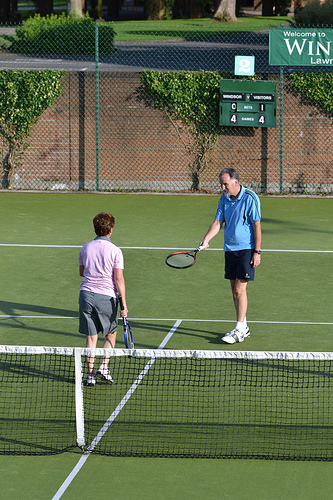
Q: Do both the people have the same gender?
A: No, they are both male and female.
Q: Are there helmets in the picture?
A: No, there are no helmets.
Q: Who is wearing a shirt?
A: The man is wearing a shirt.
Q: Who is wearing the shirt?
A: The man is wearing a shirt.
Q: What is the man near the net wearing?
A: The man is wearing a shirt.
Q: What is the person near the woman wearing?
A: The man is wearing a shirt.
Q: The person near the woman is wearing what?
A: The man is wearing a shirt.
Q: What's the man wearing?
A: The man is wearing a shirt.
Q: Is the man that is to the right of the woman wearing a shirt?
A: Yes, the man is wearing a shirt.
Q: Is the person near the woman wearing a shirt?
A: Yes, the man is wearing a shirt.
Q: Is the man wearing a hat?
A: No, the man is wearing a shirt.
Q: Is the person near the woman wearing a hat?
A: No, the man is wearing a shirt.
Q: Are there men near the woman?
A: Yes, there is a man near the woman.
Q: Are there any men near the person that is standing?
A: Yes, there is a man near the woman.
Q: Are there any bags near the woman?
A: No, there is a man near the woman.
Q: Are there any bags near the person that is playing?
A: No, there is a man near the woman.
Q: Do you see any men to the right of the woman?
A: Yes, there is a man to the right of the woman.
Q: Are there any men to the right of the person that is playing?
A: Yes, there is a man to the right of the woman.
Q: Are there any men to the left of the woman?
A: No, the man is to the right of the woman.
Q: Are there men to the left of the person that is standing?
A: No, the man is to the right of the woman.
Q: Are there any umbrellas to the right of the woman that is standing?
A: No, there is a man to the right of the woman.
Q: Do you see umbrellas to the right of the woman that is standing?
A: No, there is a man to the right of the woman.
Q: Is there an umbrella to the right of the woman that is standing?
A: No, there is a man to the right of the woman.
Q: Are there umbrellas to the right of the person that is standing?
A: No, there is a man to the right of the woman.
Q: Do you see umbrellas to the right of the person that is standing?
A: No, there is a man to the right of the woman.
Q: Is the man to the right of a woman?
A: Yes, the man is to the right of a woman.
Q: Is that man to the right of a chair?
A: No, the man is to the right of a woman.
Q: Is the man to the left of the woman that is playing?
A: No, the man is to the right of the woman.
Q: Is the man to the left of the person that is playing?
A: No, the man is to the right of the woman.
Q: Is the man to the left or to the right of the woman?
A: The man is to the right of the woman.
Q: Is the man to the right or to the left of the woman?
A: The man is to the right of the woman.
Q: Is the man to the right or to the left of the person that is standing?
A: The man is to the right of the woman.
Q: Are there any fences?
A: Yes, there is a fence.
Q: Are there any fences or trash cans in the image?
A: Yes, there is a fence.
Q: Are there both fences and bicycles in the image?
A: No, there is a fence but no bicycles.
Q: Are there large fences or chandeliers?
A: Yes, there is a large fence.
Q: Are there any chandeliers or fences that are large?
A: Yes, the fence is large.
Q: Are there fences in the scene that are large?
A: Yes, there is a large fence.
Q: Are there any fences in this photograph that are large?
A: Yes, there is a fence that is large.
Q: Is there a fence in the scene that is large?
A: Yes, there is a fence that is large.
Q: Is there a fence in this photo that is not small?
A: Yes, there is a large fence.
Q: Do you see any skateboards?
A: No, there are no skateboards.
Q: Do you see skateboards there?
A: No, there are no skateboards.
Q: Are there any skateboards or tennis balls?
A: No, there are no skateboards or tennis balls.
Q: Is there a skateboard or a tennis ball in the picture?
A: No, there are no skateboards or tennis balls.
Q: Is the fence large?
A: Yes, the fence is large.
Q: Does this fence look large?
A: Yes, the fence is large.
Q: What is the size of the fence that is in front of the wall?
A: The fence is large.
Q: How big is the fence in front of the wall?
A: The fence is large.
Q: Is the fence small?
A: No, the fence is large.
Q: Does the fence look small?
A: No, the fence is large.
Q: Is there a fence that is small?
A: No, there is a fence but it is large.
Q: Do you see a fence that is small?
A: No, there is a fence but it is large.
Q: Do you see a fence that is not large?
A: No, there is a fence but it is large.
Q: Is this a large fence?
A: Yes, this is a large fence.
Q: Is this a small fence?
A: No, this is a large fence.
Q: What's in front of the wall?
A: The fence is in front of the wall.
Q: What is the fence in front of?
A: The fence is in front of the wall.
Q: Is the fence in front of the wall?
A: Yes, the fence is in front of the wall.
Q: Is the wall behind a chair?
A: No, the wall is behind the fence.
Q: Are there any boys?
A: No, there are no boys.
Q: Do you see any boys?
A: No, there are no boys.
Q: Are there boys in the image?
A: No, there are no boys.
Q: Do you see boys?
A: No, there are no boys.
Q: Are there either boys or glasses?
A: No, there are no boys or glasses.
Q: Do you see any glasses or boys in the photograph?
A: No, there are no boys or glasses.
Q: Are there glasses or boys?
A: No, there are no boys or glasses.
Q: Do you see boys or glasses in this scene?
A: No, there are no boys or glasses.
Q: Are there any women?
A: Yes, there is a woman.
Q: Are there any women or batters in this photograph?
A: Yes, there is a woman.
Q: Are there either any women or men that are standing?
A: Yes, the woman is standing.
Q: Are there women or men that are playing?
A: Yes, the woman is playing.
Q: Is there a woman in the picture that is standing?
A: Yes, there is a woman that is standing.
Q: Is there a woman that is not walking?
A: Yes, there is a woman that is standing.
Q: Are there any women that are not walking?
A: Yes, there is a woman that is standing.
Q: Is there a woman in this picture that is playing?
A: Yes, there is a woman that is playing.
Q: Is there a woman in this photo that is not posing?
A: Yes, there is a woman that is playing.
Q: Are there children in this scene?
A: No, there are no children.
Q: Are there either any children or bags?
A: No, there are no children or bags.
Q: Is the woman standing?
A: Yes, the woman is standing.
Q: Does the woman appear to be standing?
A: Yes, the woman is standing.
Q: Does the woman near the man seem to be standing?
A: Yes, the woman is standing.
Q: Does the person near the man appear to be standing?
A: Yes, the woman is standing.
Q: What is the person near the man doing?
A: The woman is standing.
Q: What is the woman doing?
A: The woman is standing.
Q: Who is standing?
A: The woman is standing.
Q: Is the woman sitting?
A: No, the woman is standing.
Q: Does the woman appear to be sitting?
A: No, the woman is standing.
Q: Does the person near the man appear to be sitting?
A: No, the woman is standing.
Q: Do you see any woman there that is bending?
A: No, there is a woman but she is standing.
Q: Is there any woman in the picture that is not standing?
A: No, there is a woman but she is standing.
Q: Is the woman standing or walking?
A: The woman is standing.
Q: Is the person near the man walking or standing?
A: The woman is standing.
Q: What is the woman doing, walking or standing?
A: The woman is standing.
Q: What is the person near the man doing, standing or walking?
A: The woman is standing.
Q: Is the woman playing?
A: Yes, the woman is playing.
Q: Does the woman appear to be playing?
A: Yes, the woman is playing.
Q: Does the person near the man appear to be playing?
A: Yes, the woman is playing.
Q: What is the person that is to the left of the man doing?
A: The woman is playing.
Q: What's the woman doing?
A: The woman is playing.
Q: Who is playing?
A: The woman is playing.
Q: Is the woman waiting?
A: No, the woman is playing.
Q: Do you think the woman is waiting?
A: No, the woman is playing.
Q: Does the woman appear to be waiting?
A: No, the woman is playing.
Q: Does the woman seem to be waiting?
A: No, the woman is playing.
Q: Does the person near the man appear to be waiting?
A: No, the woman is playing.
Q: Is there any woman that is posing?
A: No, there is a woman but she is playing.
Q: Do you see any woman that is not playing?
A: No, there is a woman but she is playing.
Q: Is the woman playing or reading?
A: The woman is playing.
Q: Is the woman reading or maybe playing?
A: The woman is playing.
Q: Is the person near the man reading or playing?
A: The woman is playing.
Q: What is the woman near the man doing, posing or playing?
A: The woman is playing.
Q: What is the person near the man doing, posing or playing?
A: The woman is playing.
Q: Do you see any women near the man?
A: Yes, there is a woman near the man.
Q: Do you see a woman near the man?
A: Yes, there is a woman near the man.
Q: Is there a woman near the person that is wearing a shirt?
A: Yes, there is a woman near the man.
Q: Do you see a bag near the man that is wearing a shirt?
A: No, there is a woman near the man.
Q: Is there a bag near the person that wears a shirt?
A: No, there is a woman near the man.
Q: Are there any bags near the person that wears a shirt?
A: No, there is a woman near the man.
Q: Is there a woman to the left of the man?
A: Yes, there is a woman to the left of the man.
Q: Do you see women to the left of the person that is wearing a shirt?
A: Yes, there is a woman to the left of the man.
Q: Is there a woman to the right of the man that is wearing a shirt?
A: No, the woman is to the left of the man.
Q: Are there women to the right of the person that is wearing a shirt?
A: No, the woman is to the left of the man.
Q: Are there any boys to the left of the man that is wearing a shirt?
A: No, there is a woman to the left of the man.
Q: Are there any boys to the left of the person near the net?
A: No, there is a woman to the left of the man.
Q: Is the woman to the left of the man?
A: Yes, the woman is to the left of the man.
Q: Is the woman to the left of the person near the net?
A: Yes, the woman is to the left of the man.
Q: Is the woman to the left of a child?
A: No, the woman is to the left of the man.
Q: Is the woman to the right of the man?
A: No, the woman is to the left of the man.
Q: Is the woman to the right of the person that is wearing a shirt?
A: No, the woman is to the left of the man.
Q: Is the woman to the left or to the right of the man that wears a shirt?
A: The woman is to the left of the man.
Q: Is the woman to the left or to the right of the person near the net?
A: The woman is to the left of the man.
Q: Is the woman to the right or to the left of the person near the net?
A: The woman is to the left of the man.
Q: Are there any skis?
A: No, there are no skis.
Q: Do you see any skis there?
A: No, there are no skis.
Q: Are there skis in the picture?
A: No, there are no skis.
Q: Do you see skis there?
A: No, there are no skis.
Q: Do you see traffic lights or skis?
A: No, there are no skis or traffic lights.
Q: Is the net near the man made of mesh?
A: Yes, the net is made of mesh.